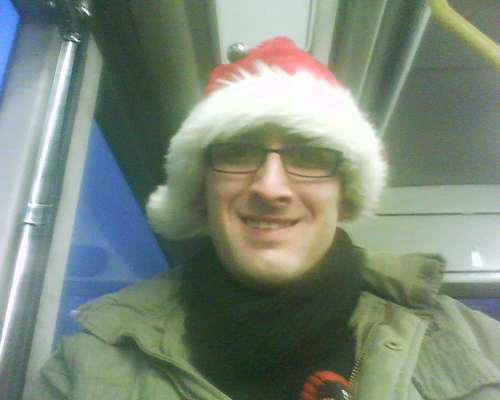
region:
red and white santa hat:
[146, 32, 388, 238]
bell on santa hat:
[226, 42, 246, 66]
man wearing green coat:
[13, 36, 497, 397]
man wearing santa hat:
[17, 33, 496, 396]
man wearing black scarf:
[12, 32, 497, 396]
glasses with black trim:
[202, 137, 344, 175]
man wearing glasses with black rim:
[146, 37, 381, 290]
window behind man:
[51, 114, 175, 356]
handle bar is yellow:
[430, 0, 497, 70]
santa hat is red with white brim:
[148, 36, 388, 287]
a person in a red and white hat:
[37, 40, 494, 393]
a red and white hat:
[144, 40, 394, 238]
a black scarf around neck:
[182, 233, 387, 384]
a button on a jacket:
[383, 336, 404, 357]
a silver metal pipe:
[9, 26, 69, 339]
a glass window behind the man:
[62, 125, 166, 304]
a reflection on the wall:
[468, 246, 489, 266]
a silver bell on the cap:
[221, 38, 253, 69]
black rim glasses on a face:
[208, 135, 351, 185]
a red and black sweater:
[297, 360, 359, 395]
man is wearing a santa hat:
[145, 34, 402, 250]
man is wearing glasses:
[204, 140, 348, 182]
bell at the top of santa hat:
[213, 33, 262, 66]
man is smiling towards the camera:
[230, 201, 331, 258]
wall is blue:
[48, 116, 199, 348]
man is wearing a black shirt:
[191, 235, 396, 397]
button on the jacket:
[375, 321, 416, 358]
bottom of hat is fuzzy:
[152, 55, 384, 265]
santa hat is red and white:
[135, 25, 408, 240]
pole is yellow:
[439, 0, 499, 64]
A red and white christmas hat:
[140, 30, 393, 235]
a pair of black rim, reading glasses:
[202, 135, 352, 179]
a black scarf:
[161, 235, 388, 399]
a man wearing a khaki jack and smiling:
[17, 42, 489, 399]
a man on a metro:
[125, 23, 496, 344]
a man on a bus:
[10, 31, 437, 398]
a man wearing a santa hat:
[122, 33, 390, 291]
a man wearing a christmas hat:
[141, 32, 406, 282]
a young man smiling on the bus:
[47, 38, 498, 398]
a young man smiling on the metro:
[48, 38, 498, 399]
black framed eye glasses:
[208, 133, 342, 178]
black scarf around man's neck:
[178, 247, 372, 399]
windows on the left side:
[4, 7, 173, 352]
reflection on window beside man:
[62, 212, 143, 300]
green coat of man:
[32, 260, 499, 396]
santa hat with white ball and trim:
[135, 44, 397, 236]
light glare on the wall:
[466, 249, 482, 266]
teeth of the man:
[242, 212, 290, 233]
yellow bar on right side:
[429, 5, 499, 73]